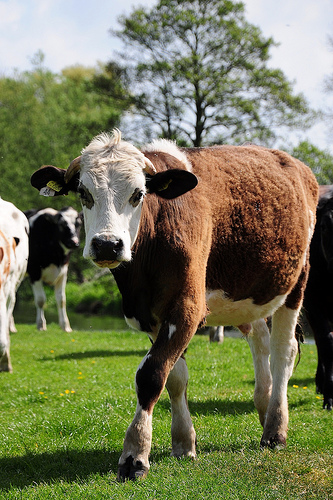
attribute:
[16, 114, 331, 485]
cow — brown, white, black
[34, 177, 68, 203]
tags — yellow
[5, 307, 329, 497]
field — short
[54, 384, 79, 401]
flower — yellow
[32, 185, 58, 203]
tag — white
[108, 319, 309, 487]
lower leg — white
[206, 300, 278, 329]
belly — white, soft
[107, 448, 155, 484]
hoof — black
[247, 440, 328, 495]
dandelions — yellow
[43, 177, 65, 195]
tag — yellow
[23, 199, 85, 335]
cow — leg